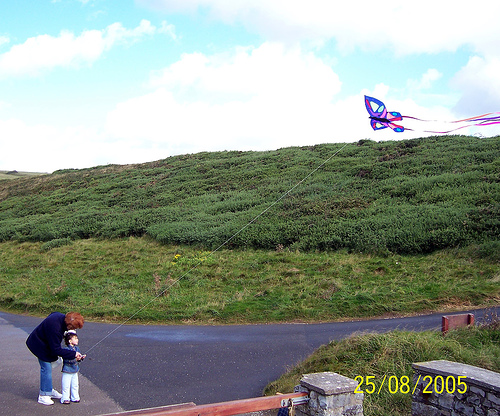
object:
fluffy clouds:
[0, 0, 499, 103]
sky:
[0, 0, 497, 169]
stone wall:
[410, 359, 500, 415]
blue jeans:
[39, 359, 52, 396]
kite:
[364, 94, 500, 135]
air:
[0, 62, 100, 132]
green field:
[0, 137, 500, 252]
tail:
[401, 113, 499, 132]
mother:
[24, 311, 82, 405]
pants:
[58, 373, 79, 404]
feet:
[37, 394, 55, 405]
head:
[65, 312, 84, 330]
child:
[61, 330, 87, 404]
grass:
[0, 236, 156, 310]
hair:
[65, 311, 84, 330]